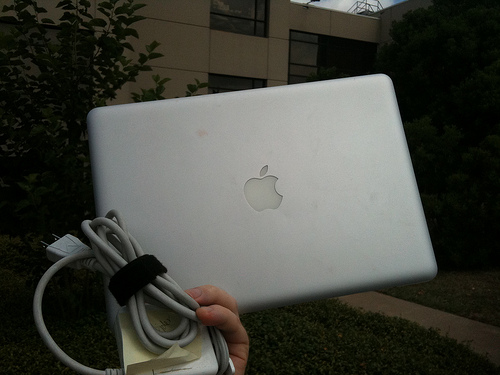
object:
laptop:
[86, 73, 438, 311]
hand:
[184, 285, 252, 375]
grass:
[0, 234, 492, 373]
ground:
[0, 270, 498, 374]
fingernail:
[198, 304, 212, 310]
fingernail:
[185, 286, 204, 300]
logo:
[244, 165, 283, 213]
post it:
[119, 303, 204, 375]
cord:
[33, 210, 230, 374]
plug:
[40, 232, 92, 271]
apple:
[243, 163, 283, 212]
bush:
[0, 0, 230, 324]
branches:
[71, 0, 84, 126]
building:
[0, 0, 434, 106]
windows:
[210, 73, 268, 94]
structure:
[345, 55, 383, 72]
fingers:
[193, 304, 251, 363]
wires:
[35, 208, 230, 375]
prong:
[38, 232, 61, 247]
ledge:
[315, 291, 499, 366]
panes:
[287, 64, 317, 79]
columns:
[172, 100, 174, 104]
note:
[148, 314, 174, 334]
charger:
[37, 233, 97, 271]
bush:
[0, 298, 500, 375]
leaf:
[295, 344, 313, 351]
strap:
[108, 253, 168, 308]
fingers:
[184, 286, 239, 320]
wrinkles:
[227, 334, 249, 361]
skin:
[228, 342, 248, 349]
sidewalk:
[335, 290, 500, 368]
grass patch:
[376, 267, 499, 324]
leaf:
[147, 52, 164, 60]